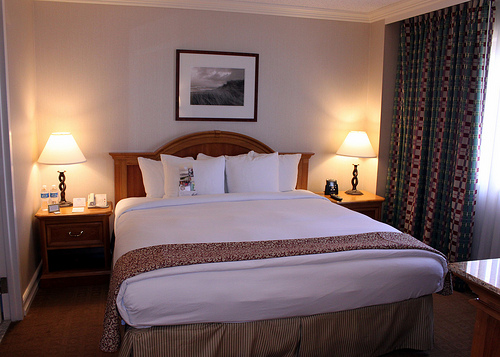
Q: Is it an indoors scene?
A: Yes, it is indoors.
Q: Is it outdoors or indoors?
A: It is indoors.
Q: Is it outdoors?
A: No, it is indoors.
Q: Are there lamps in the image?
A: Yes, there is a lamp.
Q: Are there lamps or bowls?
A: Yes, there is a lamp.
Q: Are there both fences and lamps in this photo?
A: No, there is a lamp but no fences.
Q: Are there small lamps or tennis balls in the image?
A: Yes, there is a small lamp.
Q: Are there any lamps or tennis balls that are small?
A: Yes, the lamp is small.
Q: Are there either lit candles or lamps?
A: Yes, there is a lit lamp.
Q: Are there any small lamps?
A: Yes, there is a small lamp.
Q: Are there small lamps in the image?
A: Yes, there is a small lamp.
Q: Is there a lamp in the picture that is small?
A: Yes, there is a lamp that is small.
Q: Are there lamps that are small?
A: Yes, there is a lamp that is small.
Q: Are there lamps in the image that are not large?
A: Yes, there is a small lamp.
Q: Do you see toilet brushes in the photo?
A: No, there are no toilet brushes.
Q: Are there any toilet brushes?
A: No, there are no toilet brushes.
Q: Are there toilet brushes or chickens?
A: No, there are no toilet brushes or chickens.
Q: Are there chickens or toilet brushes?
A: No, there are no toilet brushes or chickens.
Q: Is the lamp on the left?
A: Yes, the lamp is on the left of the image.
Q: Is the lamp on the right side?
A: No, the lamp is on the left of the image.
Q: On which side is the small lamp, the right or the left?
A: The lamp is on the left of the image.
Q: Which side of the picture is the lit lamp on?
A: The lamp is on the left of the image.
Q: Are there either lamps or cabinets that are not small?
A: No, there is a lamp but it is small.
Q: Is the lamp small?
A: Yes, the lamp is small.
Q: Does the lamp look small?
A: Yes, the lamp is small.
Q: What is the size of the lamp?
A: The lamp is small.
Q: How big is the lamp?
A: The lamp is small.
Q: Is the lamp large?
A: No, the lamp is small.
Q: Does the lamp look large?
A: No, the lamp is small.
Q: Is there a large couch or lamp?
A: No, there is a lamp but it is small.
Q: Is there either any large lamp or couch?
A: No, there is a lamp but it is small.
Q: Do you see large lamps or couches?
A: No, there is a lamp but it is small.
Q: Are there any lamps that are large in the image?
A: No, there is a lamp but it is small.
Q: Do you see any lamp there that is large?
A: No, there is a lamp but it is small.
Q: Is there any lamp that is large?
A: No, there is a lamp but it is small.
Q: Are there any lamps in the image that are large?
A: No, there is a lamp but it is small.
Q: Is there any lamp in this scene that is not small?
A: No, there is a lamp but it is small.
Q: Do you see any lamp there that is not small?
A: No, there is a lamp but it is small.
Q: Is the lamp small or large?
A: The lamp is small.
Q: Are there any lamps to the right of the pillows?
A: No, the lamp is to the left of the pillows.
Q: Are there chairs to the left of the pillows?
A: No, there is a lamp to the left of the pillows.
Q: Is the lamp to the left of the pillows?
A: Yes, the lamp is to the left of the pillows.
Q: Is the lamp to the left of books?
A: No, the lamp is to the left of the pillows.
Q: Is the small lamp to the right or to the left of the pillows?
A: The lamp is to the left of the pillows.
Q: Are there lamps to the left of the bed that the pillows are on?
A: Yes, there is a lamp to the left of the bed.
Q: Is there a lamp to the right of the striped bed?
A: No, the lamp is to the left of the bed.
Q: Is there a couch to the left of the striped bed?
A: No, there is a lamp to the left of the bed.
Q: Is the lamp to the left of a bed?
A: Yes, the lamp is to the left of a bed.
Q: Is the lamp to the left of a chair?
A: No, the lamp is to the left of a bed.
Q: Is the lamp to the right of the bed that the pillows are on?
A: No, the lamp is to the left of the bed.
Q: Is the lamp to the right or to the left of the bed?
A: The lamp is to the left of the bed.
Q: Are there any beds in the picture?
A: Yes, there is a bed.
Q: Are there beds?
A: Yes, there is a bed.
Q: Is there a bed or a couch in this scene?
A: Yes, there is a bed.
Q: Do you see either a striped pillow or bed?
A: Yes, there is a striped bed.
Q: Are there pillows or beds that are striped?
A: Yes, the bed is striped.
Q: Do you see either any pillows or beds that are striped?
A: Yes, the bed is striped.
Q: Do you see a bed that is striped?
A: Yes, there is a striped bed.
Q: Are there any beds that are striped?
A: Yes, there is a bed that is striped.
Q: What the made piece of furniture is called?
A: The piece of furniture is a bed.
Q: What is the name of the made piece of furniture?
A: The piece of furniture is a bed.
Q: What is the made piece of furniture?
A: The piece of furniture is a bed.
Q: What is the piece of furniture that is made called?
A: The piece of furniture is a bed.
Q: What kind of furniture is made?
A: The furniture is a bed.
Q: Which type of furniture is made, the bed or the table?
A: The bed is made.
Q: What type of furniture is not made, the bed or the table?
A: The table is not made.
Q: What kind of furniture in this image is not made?
A: The furniture is a table.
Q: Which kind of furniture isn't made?
A: The furniture is a table.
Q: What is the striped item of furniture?
A: The piece of furniture is a bed.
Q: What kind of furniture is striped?
A: The furniture is a bed.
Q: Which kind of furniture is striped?
A: The furniture is a bed.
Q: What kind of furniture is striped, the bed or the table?
A: The bed is striped.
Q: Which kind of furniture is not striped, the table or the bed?
A: The table is not striped.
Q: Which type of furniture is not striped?
A: The furniture is a table.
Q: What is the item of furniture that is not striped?
A: The piece of furniture is a table.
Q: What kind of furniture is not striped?
A: The furniture is a table.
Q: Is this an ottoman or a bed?
A: This is a bed.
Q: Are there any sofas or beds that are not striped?
A: No, there is a bed but it is striped.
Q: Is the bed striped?
A: Yes, the bed is striped.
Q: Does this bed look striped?
A: Yes, the bed is striped.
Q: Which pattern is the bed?
A: The bed is striped.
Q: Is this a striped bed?
A: Yes, this is a striped bed.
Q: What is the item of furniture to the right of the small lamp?
A: The piece of furniture is a bed.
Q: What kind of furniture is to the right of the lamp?
A: The piece of furniture is a bed.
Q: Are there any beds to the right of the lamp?
A: Yes, there is a bed to the right of the lamp.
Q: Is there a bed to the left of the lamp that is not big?
A: No, the bed is to the right of the lamp.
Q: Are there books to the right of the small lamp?
A: No, there is a bed to the right of the lamp.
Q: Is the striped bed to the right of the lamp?
A: Yes, the bed is to the right of the lamp.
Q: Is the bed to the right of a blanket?
A: No, the bed is to the right of the lamp.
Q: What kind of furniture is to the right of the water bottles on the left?
A: The piece of furniture is a bed.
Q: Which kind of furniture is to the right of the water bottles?
A: The piece of furniture is a bed.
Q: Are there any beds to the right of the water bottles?
A: Yes, there is a bed to the right of the water bottles.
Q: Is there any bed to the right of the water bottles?
A: Yes, there is a bed to the right of the water bottles.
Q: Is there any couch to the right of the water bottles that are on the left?
A: No, there is a bed to the right of the water bottles.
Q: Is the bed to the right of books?
A: No, the bed is to the right of the water bottles.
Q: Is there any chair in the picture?
A: No, there are no chairs.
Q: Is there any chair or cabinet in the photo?
A: No, there are no chairs or cabinets.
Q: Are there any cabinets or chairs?
A: No, there are no chairs or cabinets.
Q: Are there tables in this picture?
A: Yes, there is a table.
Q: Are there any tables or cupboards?
A: Yes, there is a table.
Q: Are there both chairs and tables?
A: No, there is a table but no chairs.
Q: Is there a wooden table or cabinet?
A: Yes, there is a wood table.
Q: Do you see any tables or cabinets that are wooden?
A: Yes, the table is wooden.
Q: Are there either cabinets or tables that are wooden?
A: Yes, the table is wooden.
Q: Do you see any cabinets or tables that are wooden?
A: Yes, the table is wooden.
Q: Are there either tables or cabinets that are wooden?
A: Yes, the table is wooden.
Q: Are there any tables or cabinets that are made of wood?
A: Yes, the table is made of wood.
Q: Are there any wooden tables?
A: Yes, there is a wood table.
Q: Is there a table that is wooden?
A: Yes, there is a table that is wooden.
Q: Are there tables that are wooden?
A: Yes, there is a table that is wooden.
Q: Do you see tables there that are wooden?
A: Yes, there is a table that is wooden.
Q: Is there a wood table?
A: Yes, there is a table that is made of wood.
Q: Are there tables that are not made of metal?
A: Yes, there is a table that is made of wood.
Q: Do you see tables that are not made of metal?
A: Yes, there is a table that is made of wood.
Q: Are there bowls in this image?
A: No, there are no bowls.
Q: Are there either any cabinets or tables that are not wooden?
A: No, there is a table but it is wooden.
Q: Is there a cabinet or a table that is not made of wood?
A: No, there is a table but it is made of wood.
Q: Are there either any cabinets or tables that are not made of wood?
A: No, there is a table but it is made of wood.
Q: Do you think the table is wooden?
A: Yes, the table is wooden.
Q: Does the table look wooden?
A: Yes, the table is wooden.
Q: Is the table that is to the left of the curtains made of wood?
A: Yes, the table is made of wood.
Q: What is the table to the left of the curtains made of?
A: The table is made of wood.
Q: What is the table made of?
A: The table is made of wood.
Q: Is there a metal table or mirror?
A: No, there is a table but it is wooden.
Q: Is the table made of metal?
A: No, the table is made of wood.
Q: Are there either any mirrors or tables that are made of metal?
A: No, there is a table but it is made of wood.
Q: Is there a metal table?
A: No, there is a table but it is made of wood.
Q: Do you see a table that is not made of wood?
A: No, there is a table but it is made of wood.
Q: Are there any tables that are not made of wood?
A: No, there is a table but it is made of wood.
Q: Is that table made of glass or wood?
A: The table is made of wood.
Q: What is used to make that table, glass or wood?
A: The table is made of wood.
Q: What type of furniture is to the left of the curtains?
A: The piece of furniture is a table.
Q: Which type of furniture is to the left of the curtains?
A: The piece of furniture is a table.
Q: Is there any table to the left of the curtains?
A: Yes, there is a table to the left of the curtains.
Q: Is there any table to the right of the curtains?
A: No, the table is to the left of the curtains.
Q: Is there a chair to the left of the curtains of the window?
A: No, there is a table to the left of the curtains.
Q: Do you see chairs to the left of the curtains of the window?
A: No, there is a table to the left of the curtains.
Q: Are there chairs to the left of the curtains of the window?
A: No, there is a table to the left of the curtains.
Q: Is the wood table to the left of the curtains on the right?
A: Yes, the table is to the left of the curtains.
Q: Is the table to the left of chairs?
A: No, the table is to the left of the curtains.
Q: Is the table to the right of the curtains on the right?
A: No, the table is to the left of the curtains.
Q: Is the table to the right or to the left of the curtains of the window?
A: The table is to the left of the curtains.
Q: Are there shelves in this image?
A: No, there are no shelves.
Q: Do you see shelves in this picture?
A: No, there are no shelves.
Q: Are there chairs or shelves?
A: No, there are no shelves or chairs.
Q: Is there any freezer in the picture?
A: No, there are no refrigerators.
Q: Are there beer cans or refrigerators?
A: No, there are no refrigerators or beer cans.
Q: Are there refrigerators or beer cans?
A: No, there are no refrigerators or beer cans.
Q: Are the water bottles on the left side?
A: Yes, the water bottles are on the left of the image.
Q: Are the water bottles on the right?
A: No, the water bottles are on the left of the image.